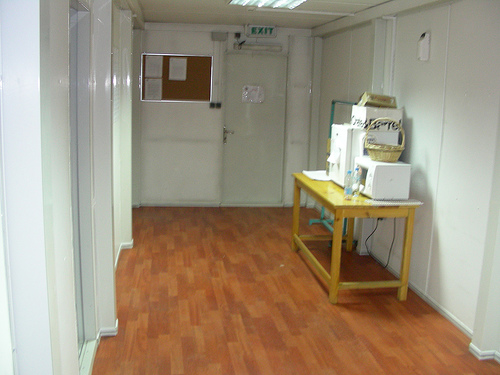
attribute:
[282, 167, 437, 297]
table — wooden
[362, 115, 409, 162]
basket — woven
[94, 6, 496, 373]
hallway — empty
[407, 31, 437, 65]
paper — hanging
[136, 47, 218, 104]
cork board — hanging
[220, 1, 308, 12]
light — flourescent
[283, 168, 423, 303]
table — wooden, brown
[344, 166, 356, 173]
tops — blue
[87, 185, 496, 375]
floors — wooden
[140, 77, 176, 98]
paper — posted